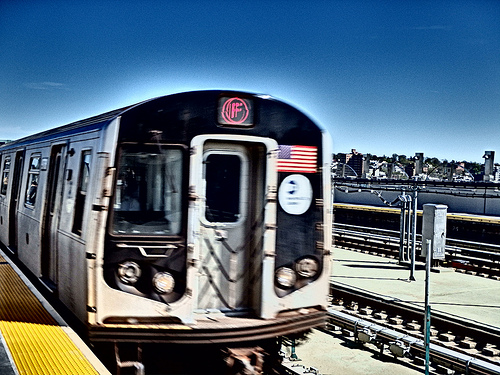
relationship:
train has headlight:
[1, 89, 332, 348] [294, 257, 320, 281]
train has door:
[1, 89, 332, 348] [36, 135, 70, 298]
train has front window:
[1, 89, 332, 348] [105, 139, 187, 240]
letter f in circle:
[231, 103, 243, 120] [221, 98, 250, 124]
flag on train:
[277, 143, 321, 173] [1, 89, 332, 348]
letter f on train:
[231, 103, 243, 120] [1, 89, 332, 348]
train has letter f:
[1, 89, 332, 348] [231, 103, 243, 120]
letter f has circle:
[231, 103, 243, 120] [221, 98, 250, 124]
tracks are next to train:
[323, 280, 499, 375] [1, 89, 332, 348]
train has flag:
[1, 89, 332, 348] [277, 143, 321, 173]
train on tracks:
[1, 89, 332, 348] [323, 280, 499, 375]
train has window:
[1, 89, 332, 348] [68, 147, 94, 239]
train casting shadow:
[1, 89, 332, 348] [1, 254, 68, 326]